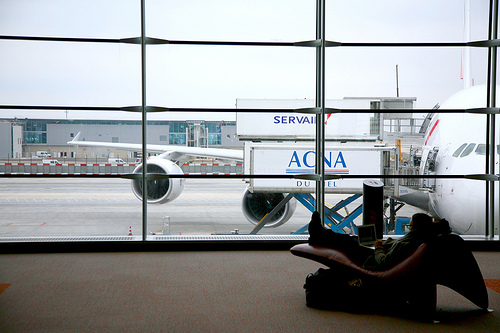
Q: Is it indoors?
A: Yes, it is indoors.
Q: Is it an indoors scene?
A: Yes, it is indoors.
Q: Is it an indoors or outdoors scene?
A: It is indoors.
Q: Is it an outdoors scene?
A: No, it is indoors.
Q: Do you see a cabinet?
A: No, there are no cabinets.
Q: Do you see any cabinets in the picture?
A: No, there are no cabinets.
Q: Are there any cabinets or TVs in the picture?
A: No, there are no cabinets or tvs.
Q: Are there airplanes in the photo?
A: Yes, there is an airplane.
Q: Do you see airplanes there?
A: Yes, there is an airplane.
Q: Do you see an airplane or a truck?
A: Yes, there is an airplane.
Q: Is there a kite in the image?
A: No, there are no kites.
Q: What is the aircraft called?
A: The aircraft is an airplane.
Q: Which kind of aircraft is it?
A: The aircraft is an airplane.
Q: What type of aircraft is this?
A: That is an airplane.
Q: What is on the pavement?
A: The airplane is on the pavement.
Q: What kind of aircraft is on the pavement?
A: The aircraft is an airplane.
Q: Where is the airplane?
A: The airplane is on the pavement.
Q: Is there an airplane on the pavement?
A: Yes, there is an airplane on the pavement.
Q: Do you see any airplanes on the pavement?
A: Yes, there is an airplane on the pavement.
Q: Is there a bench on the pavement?
A: No, there is an airplane on the pavement.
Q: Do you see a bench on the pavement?
A: No, there is an airplane on the pavement.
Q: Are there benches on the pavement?
A: No, there is an airplane on the pavement.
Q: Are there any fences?
A: No, there are no fences.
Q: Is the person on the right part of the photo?
A: Yes, the person is on the right of the image.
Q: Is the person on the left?
A: No, the person is on the right of the image.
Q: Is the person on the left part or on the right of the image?
A: The person is on the right of the image.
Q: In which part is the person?
A: The person is on the right of the image.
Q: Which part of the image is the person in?
A: The person is on the right of the image.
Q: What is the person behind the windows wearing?
A: The person is wearing a shirt.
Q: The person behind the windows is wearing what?
A: The person is wearing a shirt.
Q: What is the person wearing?
A: The person is wearing a shirt.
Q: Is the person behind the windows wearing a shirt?
A: Yes, the person is wearing a shirt.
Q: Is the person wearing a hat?
A: No, the person is wearing a shirt.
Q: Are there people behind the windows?
A: Yes, there is a person behind the windows.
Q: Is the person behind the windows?
A: Yes, the person is behind the windows.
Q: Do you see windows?
A: Yes, there are windows.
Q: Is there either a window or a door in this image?
A: Yes, there are windows.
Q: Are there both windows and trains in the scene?
A: No, there are windows but no trains.